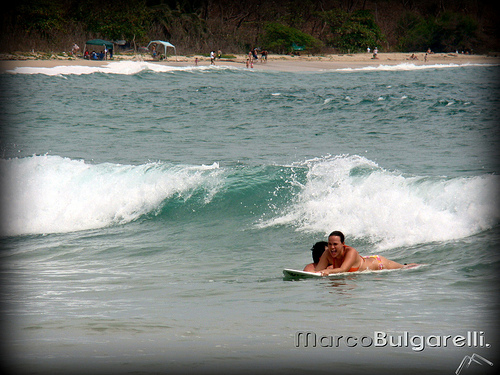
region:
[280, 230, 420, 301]
woman surfing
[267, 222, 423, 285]
woman laying down while surfing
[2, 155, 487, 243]
waves crashing behind woman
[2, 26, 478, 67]
people on a beach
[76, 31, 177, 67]
tents set up on the beach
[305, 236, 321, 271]
person helping the woman surf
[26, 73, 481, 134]
waves in the ocean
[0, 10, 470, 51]
trees on the shore of the beach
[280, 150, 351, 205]
splashing from the waves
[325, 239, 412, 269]
woman wearing a bikini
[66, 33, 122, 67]
A green canopy tent on a beach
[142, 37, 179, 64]
A white canopy tent on a beach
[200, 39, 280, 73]
People in the distance on the shore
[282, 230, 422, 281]
Woman laying on a surfboard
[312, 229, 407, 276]
Woman in a bikini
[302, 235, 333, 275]
Man in water next to woman on a surfboard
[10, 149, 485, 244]
A small wave crashing over in the water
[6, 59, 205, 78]
Sea foam washing ashore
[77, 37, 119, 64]
A group of people lounging under a canopy tent on a beach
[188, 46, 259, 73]
Adults with children standing at the water's edge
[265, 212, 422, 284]
person on board in ocean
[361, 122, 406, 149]
white and green ocean waves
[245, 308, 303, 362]
white and green ocean waves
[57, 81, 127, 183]
white and green ocean waves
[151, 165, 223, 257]
white and green ocean waves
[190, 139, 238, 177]
white and green ocean waves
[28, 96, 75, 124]
Small ripples in the water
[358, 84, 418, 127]
Small ripples in the water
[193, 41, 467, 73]
People standing on the beach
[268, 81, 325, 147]
Small ripples in the water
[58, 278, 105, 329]
Small ripples in the water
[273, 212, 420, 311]
Woman laying on a surboard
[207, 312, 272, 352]
Small ripples in the water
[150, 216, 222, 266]
Small ripples in the water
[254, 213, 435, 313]
a woman on the surfboard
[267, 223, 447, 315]
a woman on the surfboard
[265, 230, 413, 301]
a woman on the surfboard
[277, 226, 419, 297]
a woman on the surfboard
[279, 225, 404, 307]
a woman on the surfboard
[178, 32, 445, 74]
people at the shore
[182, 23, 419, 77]
people at the shore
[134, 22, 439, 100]
people at the shore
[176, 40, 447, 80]
people at the shore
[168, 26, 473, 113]
people at the shore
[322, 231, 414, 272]
girl on a surfboard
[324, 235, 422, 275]
surfboard has a woman on it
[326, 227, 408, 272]
woman is wearing a bikini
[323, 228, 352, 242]
woman has hair on her head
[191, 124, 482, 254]
the water is making a wave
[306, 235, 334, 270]
man is swimming in the water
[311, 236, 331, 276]
man is holding onto surfboard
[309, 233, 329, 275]
man is next to woman on surfboard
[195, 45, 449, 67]
people on the beach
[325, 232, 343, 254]
person has a head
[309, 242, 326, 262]
person has a head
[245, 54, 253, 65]
person is on the beach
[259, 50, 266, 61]
person is on the beach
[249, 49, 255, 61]
person is on the beach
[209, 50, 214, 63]
person is on the beach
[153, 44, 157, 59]
person is on the beach